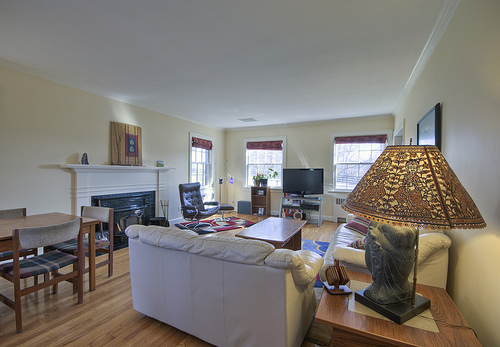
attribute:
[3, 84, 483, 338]
room — living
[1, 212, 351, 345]
floor — wooden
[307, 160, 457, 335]
lamp — electric lamp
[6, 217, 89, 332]
chair — wooden, plaid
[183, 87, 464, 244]
wall — white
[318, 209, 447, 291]
couch — white and leather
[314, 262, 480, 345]
table — brown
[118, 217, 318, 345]
couch — white and leather, white, wooden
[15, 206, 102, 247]
table — dining table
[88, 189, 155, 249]
fireplace — black, engraved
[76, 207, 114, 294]
chair — plaid, wooden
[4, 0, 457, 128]
ceiling — white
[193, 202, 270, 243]
carpet — black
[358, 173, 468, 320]
shade — lamp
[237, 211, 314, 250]
table — coffee table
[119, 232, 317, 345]
white couch —  white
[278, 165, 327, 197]
television — kept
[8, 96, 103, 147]
wall — white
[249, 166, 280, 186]
plants — green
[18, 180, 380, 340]
floor — smooth and brown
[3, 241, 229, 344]
floor — wood, smooth